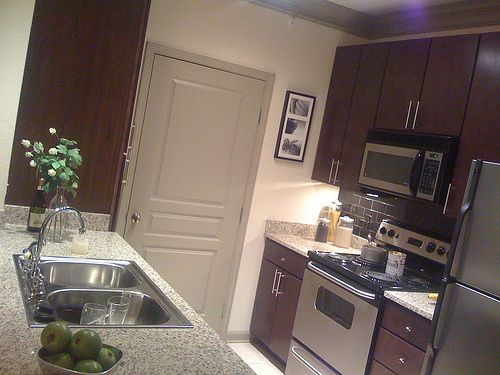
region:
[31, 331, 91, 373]
Apples in bowl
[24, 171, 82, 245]
Bottle of wine on counter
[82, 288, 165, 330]
Glasses in sink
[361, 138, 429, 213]
Microwave above stove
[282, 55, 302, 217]
Picture on wall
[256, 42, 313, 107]
Wall is painted white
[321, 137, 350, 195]
Cupboards have silver handles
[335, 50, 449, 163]
Cupboards are brown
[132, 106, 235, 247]
Door is gray in color with silver door knob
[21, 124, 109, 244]
Flowers in clear glass vase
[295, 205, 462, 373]
Electric stove with stainless steel accents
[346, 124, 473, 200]
in cabinet microwave oven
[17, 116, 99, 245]
vace with white roses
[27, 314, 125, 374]
green apples in a bowl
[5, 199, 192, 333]
stainless steel sink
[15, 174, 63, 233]
corked bottle of wine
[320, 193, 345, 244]
jar of pasta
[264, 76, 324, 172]
tri framed picture on a wall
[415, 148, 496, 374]
stainless steel fridge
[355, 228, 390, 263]
metal pot on an electric stove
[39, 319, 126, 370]
The green apples in a bowl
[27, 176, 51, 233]
The wine bottle on the counter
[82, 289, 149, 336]
The glasses in the sink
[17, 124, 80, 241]
The flowers in the vase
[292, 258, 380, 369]
The face of the stove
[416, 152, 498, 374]
The refrigerator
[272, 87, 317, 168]
The photo hanging on the wall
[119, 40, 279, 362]
The doorway shown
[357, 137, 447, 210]
The microwave above the stove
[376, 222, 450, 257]
The dials on the stove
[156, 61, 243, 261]
taupe colored kitchen door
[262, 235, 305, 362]
brown chocolate cabinets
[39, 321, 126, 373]
bowl of green apples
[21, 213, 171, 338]
stainless steel kitchen faucet and sink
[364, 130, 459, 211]
microwave in cabinets on wall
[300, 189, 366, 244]
large glass jars of food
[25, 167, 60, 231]
green and white wine bottle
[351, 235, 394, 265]
silver pot on stove cooking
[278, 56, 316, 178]
black and white art work on the wall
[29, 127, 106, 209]
green and white plant in vase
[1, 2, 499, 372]
somebody's kitchen that is nicely decorated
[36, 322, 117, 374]
a bowl full of green apples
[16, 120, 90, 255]
a vase filled with white flowers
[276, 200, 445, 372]
an oven by the counters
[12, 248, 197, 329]
a silver sink on the counter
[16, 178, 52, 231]
a bottle of wine by the flowers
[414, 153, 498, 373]
a stainless steeel fridge by the counter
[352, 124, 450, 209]
a microwave above the stove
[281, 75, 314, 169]
a picture on the wall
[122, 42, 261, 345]
a door for the kitchen